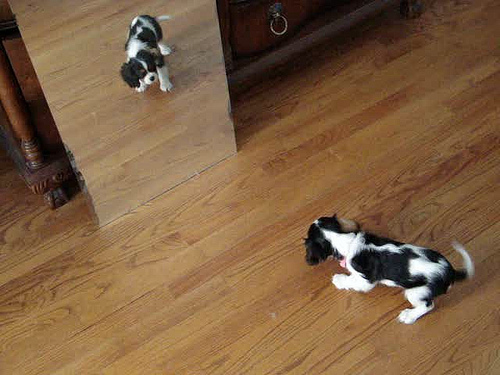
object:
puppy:
[294, 208, 483, 334]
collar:
[332, 228, 358, 268]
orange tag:
[337, 256, 347, 273]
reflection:
[121, 15, 176, 99]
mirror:
[7, 0, 241, 232]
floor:
[2, 205, 243, 372]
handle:
[269, 4, 289, 36]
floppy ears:
[299, 215, 356, 264]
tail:
[445, 239, 477, 287]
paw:
[332, 273, 352, 288]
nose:
[149, 73, 156, 84]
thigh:
[405, 286, 438, 309]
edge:
[333, 285, 350, 292]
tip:
[451, 240, 465, 251]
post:
[0, 42, 41, 176]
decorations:
[14, 136, 87, 211]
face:
[122, 55, 159, 90]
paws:
[385, 276, 446, 324]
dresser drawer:
[232, 1, 375, 57]